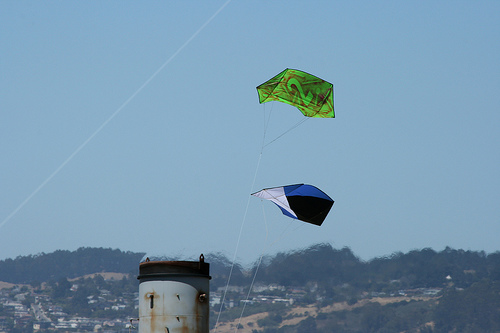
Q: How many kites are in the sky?
A: Two.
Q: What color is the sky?
A: Blue.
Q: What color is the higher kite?
A: Green.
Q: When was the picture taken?
A: Daytime.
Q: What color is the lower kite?
A: Blue.